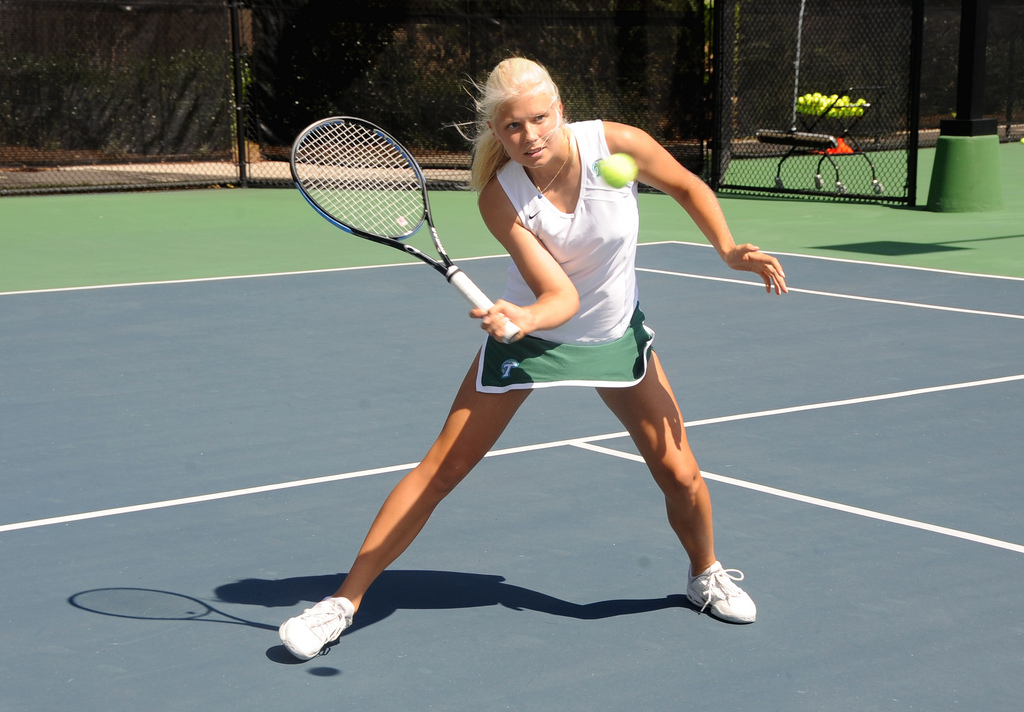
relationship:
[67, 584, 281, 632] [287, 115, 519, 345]
shadow of racket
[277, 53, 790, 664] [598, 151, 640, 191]
girl hitting ball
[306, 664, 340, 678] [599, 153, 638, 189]
shadow of ball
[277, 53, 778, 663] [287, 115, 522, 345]
girl holding racket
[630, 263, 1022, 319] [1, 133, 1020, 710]
line on tennis court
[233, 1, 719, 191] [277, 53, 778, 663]
fence behind girl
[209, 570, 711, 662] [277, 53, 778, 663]
shadow of girl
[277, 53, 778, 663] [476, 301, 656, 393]
girl wearing skirt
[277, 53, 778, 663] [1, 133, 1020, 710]
girl on tennis court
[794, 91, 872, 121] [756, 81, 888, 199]
tennis balls in cart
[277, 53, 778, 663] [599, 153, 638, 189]
girl hitting ball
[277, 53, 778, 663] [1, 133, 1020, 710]
girl standing on tennis court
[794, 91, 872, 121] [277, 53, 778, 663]
tennis balls behind girl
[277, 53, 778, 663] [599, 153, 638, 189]
girl looking at ball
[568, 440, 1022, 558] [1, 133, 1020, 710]
line on tennis court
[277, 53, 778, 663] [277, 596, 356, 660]
girl wearing shoe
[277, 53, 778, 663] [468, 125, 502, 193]
girl wearing ponytail